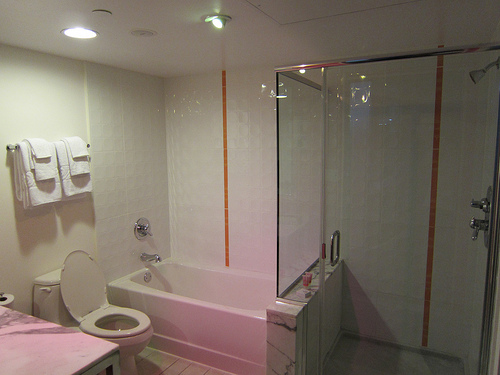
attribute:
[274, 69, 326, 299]
divider — glass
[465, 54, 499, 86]
shower head — chrome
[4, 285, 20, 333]
paper — toilet, a roll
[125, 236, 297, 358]
bathtub — white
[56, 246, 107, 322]
toilet lid — white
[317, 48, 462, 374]
door — chrome, glass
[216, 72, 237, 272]
tiles — orange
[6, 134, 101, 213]
white towels — assortment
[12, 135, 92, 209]
towels — white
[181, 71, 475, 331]
wall — open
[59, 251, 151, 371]
toilet — black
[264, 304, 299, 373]
wall tile — marble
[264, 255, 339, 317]
shelf — small, cultured, marble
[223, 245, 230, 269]
tile — orange, wall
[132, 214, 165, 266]
tub fixtures — silver colored, metal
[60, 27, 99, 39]
light — recessed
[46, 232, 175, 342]
toilet — white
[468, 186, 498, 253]
valves — chrome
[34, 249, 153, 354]
toilet — white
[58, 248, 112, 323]
lid — open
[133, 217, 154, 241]
handle — silver, single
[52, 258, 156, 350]
toilet — white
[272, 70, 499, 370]
shower — glass enclosed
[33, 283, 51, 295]
handle — white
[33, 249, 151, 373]
toilet — white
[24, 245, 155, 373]
toilet — white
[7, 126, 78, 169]
rack — silver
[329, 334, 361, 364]
tile — tan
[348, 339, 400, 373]
tile — tan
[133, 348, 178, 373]
tile — tan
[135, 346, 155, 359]
tile — tan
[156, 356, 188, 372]
tile — tan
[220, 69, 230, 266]
stripe — orange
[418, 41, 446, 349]
stripe — orange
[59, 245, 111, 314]
lid — up